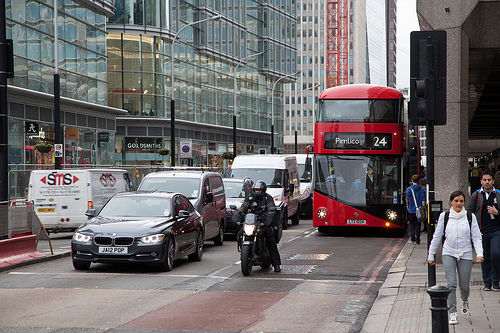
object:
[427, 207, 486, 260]
jacket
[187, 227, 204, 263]
tire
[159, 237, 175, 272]
tire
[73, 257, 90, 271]
tire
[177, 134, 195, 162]
signs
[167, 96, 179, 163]
pole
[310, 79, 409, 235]
magnet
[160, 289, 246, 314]
signs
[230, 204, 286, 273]
bike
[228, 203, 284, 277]
motorcycle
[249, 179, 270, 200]
helmet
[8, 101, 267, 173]
store fronts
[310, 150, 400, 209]
glass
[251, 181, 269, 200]
head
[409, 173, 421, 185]
head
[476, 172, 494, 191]
head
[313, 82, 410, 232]
bus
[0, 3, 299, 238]
building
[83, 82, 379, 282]
wrong picture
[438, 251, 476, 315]
pants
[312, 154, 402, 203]
window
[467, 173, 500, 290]
man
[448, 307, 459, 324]
sneakers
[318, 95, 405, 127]
window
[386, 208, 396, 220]
headlights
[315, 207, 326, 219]
headlights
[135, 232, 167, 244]
headlights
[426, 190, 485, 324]
lady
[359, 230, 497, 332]
sidewalk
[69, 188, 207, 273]
bmw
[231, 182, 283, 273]
man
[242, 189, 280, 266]
black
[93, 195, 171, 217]
windshield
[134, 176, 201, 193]
windshield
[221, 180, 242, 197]
windshield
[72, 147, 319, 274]
row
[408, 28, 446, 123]
traffic light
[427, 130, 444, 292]
pole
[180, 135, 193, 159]
direction sign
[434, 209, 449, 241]
back pack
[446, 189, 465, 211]
head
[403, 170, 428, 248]
guy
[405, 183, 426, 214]
hoodie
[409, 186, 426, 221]
bag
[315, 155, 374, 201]
reflection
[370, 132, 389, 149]
number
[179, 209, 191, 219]
mirror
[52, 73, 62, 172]
pole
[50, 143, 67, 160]
signs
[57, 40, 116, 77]
windows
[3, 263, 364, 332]
street